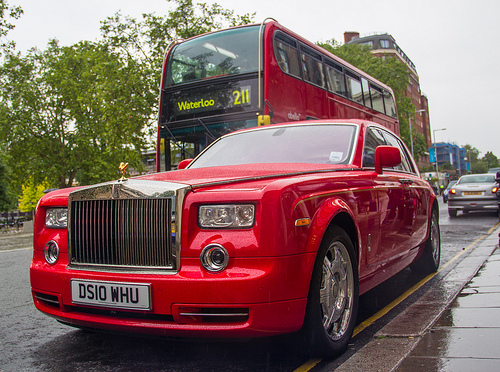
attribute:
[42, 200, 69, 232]
light — head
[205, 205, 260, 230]
light — head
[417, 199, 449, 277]
wheel — back